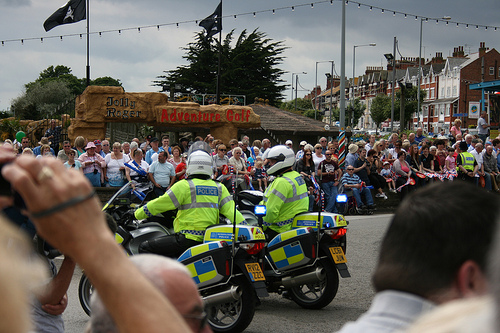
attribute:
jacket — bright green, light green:
[257, 169, 309, 233]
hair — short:
[371, 178, 498, 301]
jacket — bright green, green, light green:
[131, 177, 247, 242]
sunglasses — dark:
[301, 150, 312, 158]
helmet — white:
[186, 150, 214, 178]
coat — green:
[133, 177, 247, 243]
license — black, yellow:
[243, 259, 265, 283]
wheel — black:
[205, 270, 257, 331]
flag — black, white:
[42, 1, 86, 30]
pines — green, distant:
[151, 27, 289, 108]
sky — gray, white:
[1, 0, 498, 110]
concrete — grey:
[51, 210, 395, 330]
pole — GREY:
[333, 10, 350, 180]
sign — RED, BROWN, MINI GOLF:
[149, 98, 266, 128]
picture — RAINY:
[11, 10, 484, 317]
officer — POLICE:
[130, 145, 260, 292]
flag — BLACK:
[197, 5, 226, 35]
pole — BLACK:
[210, 31, 224, 113]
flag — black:
[42, 0, 87, 32]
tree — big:
[151, 21, 292, 107]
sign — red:
[159, 105, 252, 123]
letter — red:
[158, 106, 169, 123]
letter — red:
[167, 105, 178, 121]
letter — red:
[200, 110, 210, 120]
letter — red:
[222, 107, 235, 121]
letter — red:
[244, 108, 250, 122]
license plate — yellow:
[242, 262, 267, 281]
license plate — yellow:
[327, 243, 346, 264]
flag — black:
[198, 1, 223, 41]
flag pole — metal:
[85, 0, 90, 86]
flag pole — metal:
[217, 0, 222, 102]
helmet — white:
[182, 137, 216, 179]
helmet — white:
[260, 143, 297, 175]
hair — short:
[368, 176, 484, 296]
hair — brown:
[370, 179, 480, 300]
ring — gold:
[34, 162, 54, 180]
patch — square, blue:
[192, 183, 219, 195]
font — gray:
[193, 185, 218, 195]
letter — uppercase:
[195, 186, 201, 194]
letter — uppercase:
[200, 186, 207, 194]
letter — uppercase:
[202, 188, 209, 195]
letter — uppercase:
[208, 188, 214, 194]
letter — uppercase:
[212, 187, 219, 195]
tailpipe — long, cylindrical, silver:
[199, 280, 243, 309]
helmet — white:
[182, 149, 215, 181]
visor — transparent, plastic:
[184, 140, 213, 160]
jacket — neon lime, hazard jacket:
[133, 182, 251, 254]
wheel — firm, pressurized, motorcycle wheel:
[202, 278, 265, 326]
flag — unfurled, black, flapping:
[39, 0, 89, 34]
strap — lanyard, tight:
[25, 192, 95, 220]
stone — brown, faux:
[58, 79, 263, 160]